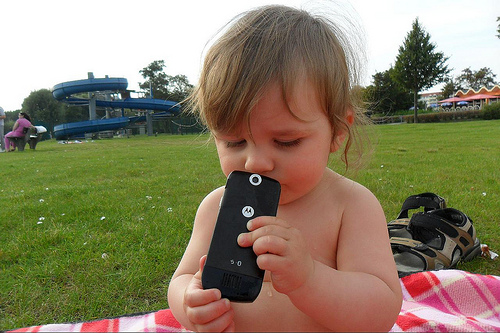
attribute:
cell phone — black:
[202, 171, 281, 308]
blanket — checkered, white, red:
[2, 269, 499, 332]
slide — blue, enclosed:
[45, 74, 185, 139]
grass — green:
[0, 114, 497, 332]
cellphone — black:
[199, 167, 279, 302]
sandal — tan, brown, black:
[385, 188, 447, 243]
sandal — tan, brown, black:
[391, 203, 481, 275]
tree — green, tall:
[386, 15, 446, 121]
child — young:
[165, 5, 407, 332]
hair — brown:
[181, 3, 379, 171]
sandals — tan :
[389, 162, 450, 283]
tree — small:
[354, 1, 475, 177]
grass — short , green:
[68, 111, 472, 268]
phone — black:
[154, 155, 285, 303]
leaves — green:
[341, 21, 461, 131]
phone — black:
[160, 146, 331, 308]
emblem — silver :
[234, 185, 256, 228]